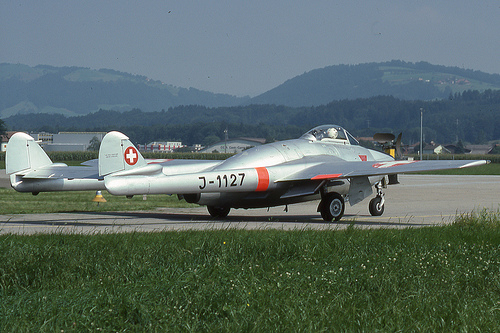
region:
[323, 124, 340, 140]
pilot in plane cockpit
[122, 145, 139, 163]
Red circle with white cross on plane stabilizer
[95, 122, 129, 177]
Rudder on rear of plane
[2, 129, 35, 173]
Rudder on rear of plane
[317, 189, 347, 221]
Rear wheel of plane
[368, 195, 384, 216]
Front wheel on plane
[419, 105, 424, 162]
Tall pole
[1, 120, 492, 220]
A silver plane on the runway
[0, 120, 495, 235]
An airfield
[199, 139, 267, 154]
An airplane hangar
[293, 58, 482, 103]
There are mountains in the background.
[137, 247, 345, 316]
The green grass is in the forefront.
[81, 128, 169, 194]
The tail of the plane has a red cross.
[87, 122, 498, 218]
The plane is silver and parked on the tarmac.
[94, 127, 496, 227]
The plane is silver, black, white and red.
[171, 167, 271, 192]
There are number and one letter on the side of the silver plane.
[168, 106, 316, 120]
There are green trees in the background.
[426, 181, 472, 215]
The tarmac is gray.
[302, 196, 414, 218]
The wheels on the plane are black.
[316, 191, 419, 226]
The wheels on the plane are small.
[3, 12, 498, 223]
mountains behind the plane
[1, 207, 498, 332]
the grass is tall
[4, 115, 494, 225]
the plane is silver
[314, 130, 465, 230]
the plane has black wheels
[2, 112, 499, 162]
buildings behind the plane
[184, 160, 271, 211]
the plane says J-1127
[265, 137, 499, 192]
the plane has a wing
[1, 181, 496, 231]
the runway is green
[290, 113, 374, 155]
someone is in the cockpit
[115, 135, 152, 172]
a red and white sign on the plane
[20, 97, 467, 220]
jet on the runway.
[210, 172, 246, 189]
1127 written on the jet.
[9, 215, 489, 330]
the grass is green.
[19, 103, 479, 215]
the jet is parked.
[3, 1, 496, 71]
the sky is blue.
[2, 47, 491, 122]
hills in the distance.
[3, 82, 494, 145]
trees in front of th ehills.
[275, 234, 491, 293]
white plants in the grass.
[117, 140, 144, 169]
red and white cross on tail.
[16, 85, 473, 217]
silver and red jet.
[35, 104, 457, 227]
Jet is on the run way.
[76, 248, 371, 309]
Grass is green color.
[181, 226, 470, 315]
Flowers are white color.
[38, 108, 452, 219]
Jet is grey color.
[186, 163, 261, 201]
J-1127 is written in the jet.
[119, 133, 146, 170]
+ sign is seen in wings.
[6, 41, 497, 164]
Mountains are behind the jet.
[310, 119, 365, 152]
One man is sitting in jet.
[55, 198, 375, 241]
Shadow falls on road.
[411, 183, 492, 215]
Road is grey color.